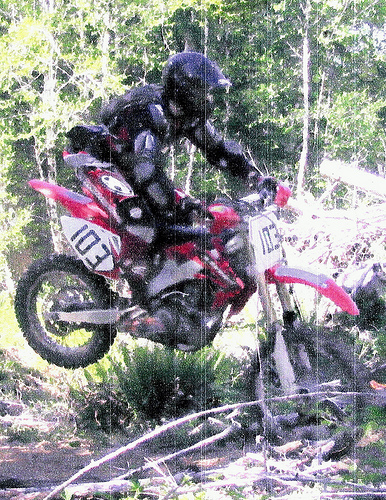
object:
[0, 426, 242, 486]
dirt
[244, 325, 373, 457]
front tire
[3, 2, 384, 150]
leaves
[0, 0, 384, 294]
trees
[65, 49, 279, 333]
bike rider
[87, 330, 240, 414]
plant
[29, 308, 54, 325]
silver spokes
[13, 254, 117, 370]
wheel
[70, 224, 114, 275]
black number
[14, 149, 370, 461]
103/on bike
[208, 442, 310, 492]
twigs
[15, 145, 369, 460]
bicycle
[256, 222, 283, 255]
numbers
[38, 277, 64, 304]
spokes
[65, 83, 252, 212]
top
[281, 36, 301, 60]
branches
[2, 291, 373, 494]
ground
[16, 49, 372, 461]
racer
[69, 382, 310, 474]
obstacle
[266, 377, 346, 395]
spokes